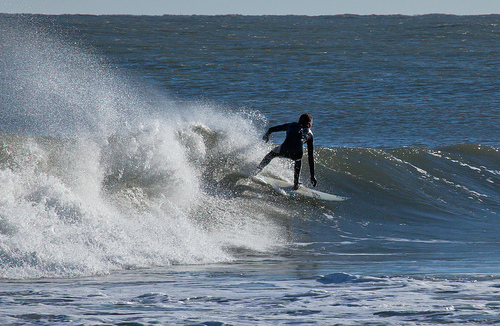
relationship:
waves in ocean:
[3, 126, 500, 272] [1, 16, 499, 325]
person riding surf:
[252, 114, 320, 191] [3, 126, 500, 272]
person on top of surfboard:
[252, 114, 320, 191] [268, 180, 352, 204]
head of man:
[298, 114, 317, 128] [252, 114, 320, 191]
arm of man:
[305, 136, 321, 187] [252, 114, 320, 191]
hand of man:
[308, 177, 321, 187] [252, 114, 320, 191]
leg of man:
[292, 163, 303, 191] [252, 114, 320, 191]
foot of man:
[293, 182, 303, 192] [252, 114, 320, 191]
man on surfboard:
[252, 114, 320, 191] [268, 180, 352, 204]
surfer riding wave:
[252, 114, 320, 191] [3, 126, 500, 272]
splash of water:
[1, 21, 162, 135] [1, 16, 499, 325]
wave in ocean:
[3, 126, 500, 272] [1, 16, 499, 325]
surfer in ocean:
[252, 114, 320, 191] [1, 16, 499, 325]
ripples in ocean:
[3, 126, 500, 272] [1, 16, 499, 325]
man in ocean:
[252, 114, 320, 191] [1, 16, 499, 325]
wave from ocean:
[3, 126, 500, 272] [1, 16, 499, 325]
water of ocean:
[3, 126, 500, 272] [1, 16, 499, 325]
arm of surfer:
[305, 136, 321, 187] [252, 114, 320, 191]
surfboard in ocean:
[268, 180, 352, 204] [1, 16, 499, 325]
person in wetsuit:
[252, 114, 320, 191] [265, 120, 314, 193]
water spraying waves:
[3, 126, 500, 272] [35, 125, 457, 241]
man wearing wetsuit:
[252, 114, 320, 191] [269, 122, 316, 172]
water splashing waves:
[14, 20, 474, 310] [14, 17, 478, 317]